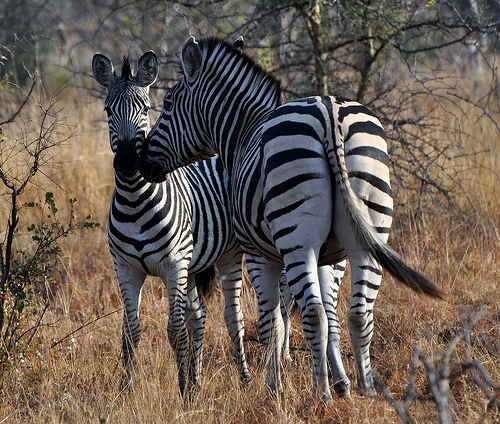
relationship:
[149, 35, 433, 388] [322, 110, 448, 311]
zebra has tail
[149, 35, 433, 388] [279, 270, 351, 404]
zebra has leg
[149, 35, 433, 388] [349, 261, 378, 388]
zebra has leg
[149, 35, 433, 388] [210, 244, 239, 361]
zebra has leg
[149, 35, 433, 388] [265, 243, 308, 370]
zebra has leg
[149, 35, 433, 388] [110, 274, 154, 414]
zebra has leg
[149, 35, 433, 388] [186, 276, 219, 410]
zebra has leg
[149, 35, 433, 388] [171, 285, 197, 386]
zebra has leg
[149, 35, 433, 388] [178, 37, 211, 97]
zebra has ear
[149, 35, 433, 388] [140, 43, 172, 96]
zebra has ear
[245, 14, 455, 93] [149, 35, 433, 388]
trees behind zebra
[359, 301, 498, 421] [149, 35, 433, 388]
twigs near zebra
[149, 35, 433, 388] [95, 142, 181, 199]
zebra has nose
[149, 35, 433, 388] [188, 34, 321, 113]
zebra has mane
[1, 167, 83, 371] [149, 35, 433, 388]
plants near zebra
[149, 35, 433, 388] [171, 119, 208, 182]
zebra has jaw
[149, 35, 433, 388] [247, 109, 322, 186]
zebra has hip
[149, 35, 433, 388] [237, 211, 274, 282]
zebra has stomach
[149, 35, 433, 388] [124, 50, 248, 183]
zebra has head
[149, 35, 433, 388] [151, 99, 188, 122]
zebra has eye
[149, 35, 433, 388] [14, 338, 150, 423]
zebra on grass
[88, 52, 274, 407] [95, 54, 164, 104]
zebra has ears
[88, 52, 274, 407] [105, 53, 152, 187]
zebra has face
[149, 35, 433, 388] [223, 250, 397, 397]
zebra has legs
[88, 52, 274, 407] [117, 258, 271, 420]
zebra has legs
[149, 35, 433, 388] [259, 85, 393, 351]
zebra has rear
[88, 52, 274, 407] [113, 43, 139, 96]
zebra has mane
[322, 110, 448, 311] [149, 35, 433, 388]
tail of zebra